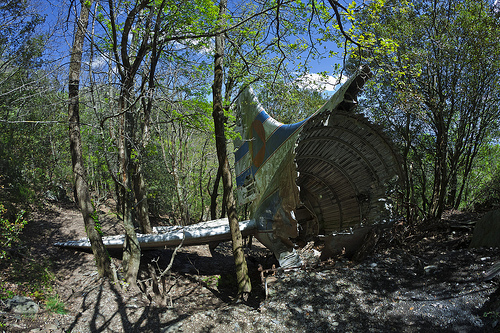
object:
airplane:
[37, 65, 405, 270]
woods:
[61, 0, 112, 277]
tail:
[47, 217, 236, 261]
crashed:
[282, 114, 412, 242]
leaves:
[349, 8, 409, 29]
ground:
[278, 281, 392, 328]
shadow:
[295, 267, 451, 321]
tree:
[97, 0, 204, 288]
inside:
[310, 157, 335, 192]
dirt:
[264, 266, 310, 294]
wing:
[232, 81, 279, 152]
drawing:
[247, 119, 267, 169]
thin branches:
[269, 0, 287, 88]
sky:
[312, 60, 331, 72]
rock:
[8, 296, 42, 320]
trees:
[334, 0, 500, 215]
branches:
[151, 1, 297, 44]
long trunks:
[207, 1, 257, 301]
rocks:
[429, 247, 491, 277]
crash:
[288, 232, 357, 269]